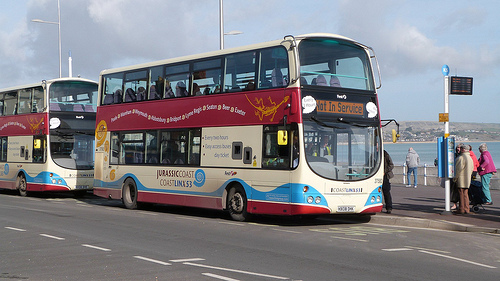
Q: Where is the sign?
A: In front of the bus.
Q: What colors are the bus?
A: Red, white and blue.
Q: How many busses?
A: 2.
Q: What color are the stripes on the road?
A: White.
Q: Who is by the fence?
A: A man.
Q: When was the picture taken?
A: Daytime.